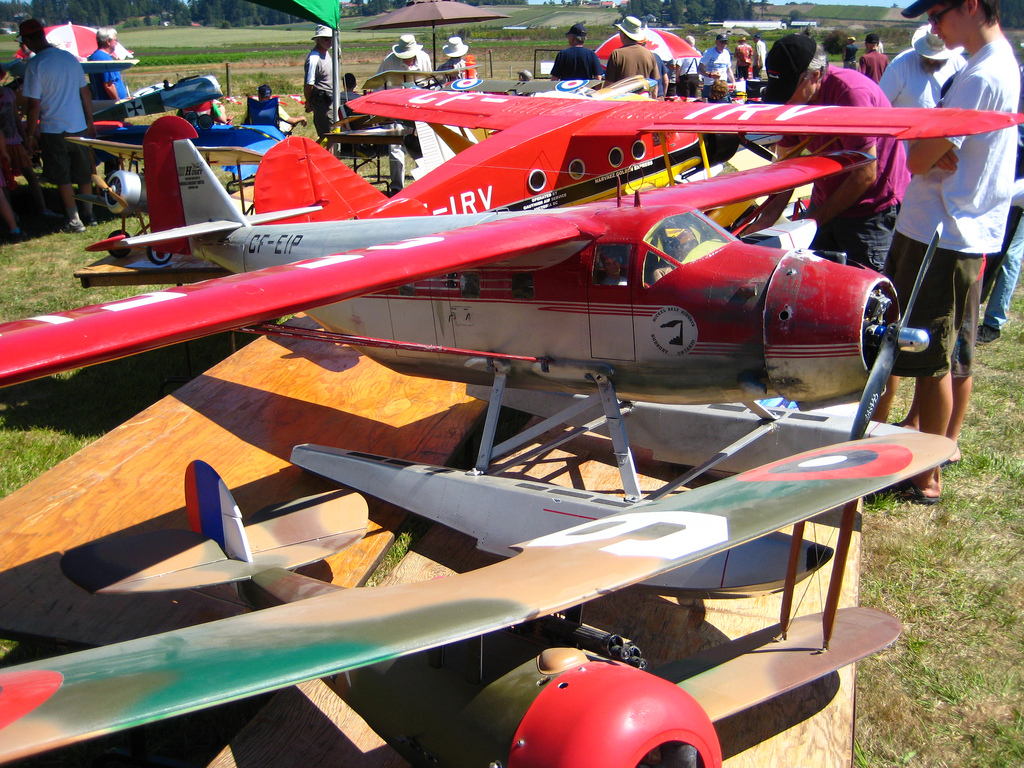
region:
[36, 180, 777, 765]
model airplanes on display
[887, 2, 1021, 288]
boy looking down at the airplanes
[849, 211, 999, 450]
propeller on the front of the red and white plane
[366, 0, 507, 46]
brown umbrella behind the airplanes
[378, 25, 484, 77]
people are wearing white hats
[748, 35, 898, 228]
man is wearing a purple shirt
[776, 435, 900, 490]
bullseye painted on the wing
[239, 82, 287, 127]
person sitting in a blue chair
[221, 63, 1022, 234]
the plane is red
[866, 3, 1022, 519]
the man has a white shirt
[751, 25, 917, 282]
man has purple top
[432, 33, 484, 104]
person wearing white hat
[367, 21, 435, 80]
person wearing white hat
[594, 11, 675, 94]
person wearing white hat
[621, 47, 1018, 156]
right wing of a plane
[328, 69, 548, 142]
right wing of a plane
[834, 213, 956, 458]
the propeller is black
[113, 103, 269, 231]
red and white stabilizer of plane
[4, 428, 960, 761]
Large colorful model plane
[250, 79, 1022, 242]
red and yellow CT-IRV model plane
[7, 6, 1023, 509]
spectator and craftsmen looking over model planes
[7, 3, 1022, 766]
model plane craft gathering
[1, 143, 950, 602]
red and white seadoo model plane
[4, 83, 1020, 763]
Three very large model planes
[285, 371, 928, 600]
landing gear for the sea Doo planes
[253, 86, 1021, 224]
The red airplane parked on the ground only reaches to the spectator's shoulders.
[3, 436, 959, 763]
The nose of the plane in front is rounded like an older model and it has green on the wings.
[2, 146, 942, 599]
The red and white airplane in the middle has landing gear of a seaplane.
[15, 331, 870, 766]
The airplanes are arranged on plywood slabs laid on the grass.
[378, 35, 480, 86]
A couple in the rear both wear white, brimmed hats in the sun.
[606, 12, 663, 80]
Another spectator wears a white brimmed hat against the sun and a brown tee shirt.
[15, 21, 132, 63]
There are red and white sun umbrellas at the back of the picture.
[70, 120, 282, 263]
another small airplane model is painted a bright royal blue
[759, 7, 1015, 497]
two casually dressed spectators examine the model planes.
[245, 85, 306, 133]
another attendant is sitting in a chair in the sun and facing away from the display.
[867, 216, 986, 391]
Man is wearing shorts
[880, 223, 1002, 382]
Man wearing shorts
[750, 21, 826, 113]
Man wearing a hat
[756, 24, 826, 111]
Man is wearing a hat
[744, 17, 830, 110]
Man wearing a black hat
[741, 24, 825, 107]
Man is wearing a black hat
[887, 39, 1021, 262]
Man wearing a shirt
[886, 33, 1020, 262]
Man wearing a white shirt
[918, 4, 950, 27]
dark black sunglasses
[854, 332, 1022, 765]
a section of green grass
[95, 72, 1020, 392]
a large red and white plane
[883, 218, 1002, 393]
a boy's green shorts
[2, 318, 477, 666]
a large wooden board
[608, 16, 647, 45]
a man's white hat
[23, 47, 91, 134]
a man's short sleeve shirt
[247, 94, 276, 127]
the back of a blue chair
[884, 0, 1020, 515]
Man wearing glasses looking at planes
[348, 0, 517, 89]
A red umbrella providing shade for people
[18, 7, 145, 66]
A red and white umbrella providing shade for people.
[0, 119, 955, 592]
Red and white model plane on a table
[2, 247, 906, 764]
The table the model planes are sitting on.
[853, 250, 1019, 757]
The grass that people are standing on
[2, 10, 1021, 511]
A group of humans looking at model planes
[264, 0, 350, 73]
A green umbrella providing shade for people.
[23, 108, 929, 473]
red and silver plane